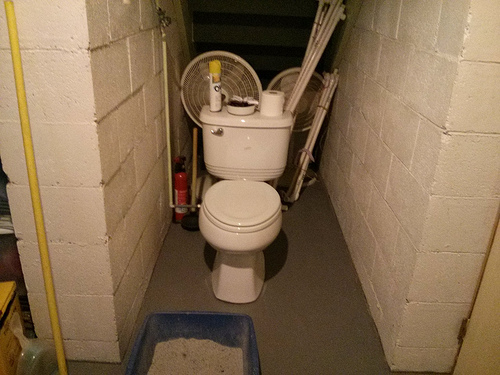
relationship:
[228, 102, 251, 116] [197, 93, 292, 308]
ashtray on top of toilet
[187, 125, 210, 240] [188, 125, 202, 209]
plunger has handle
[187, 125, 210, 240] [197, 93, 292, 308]
plunger by toilet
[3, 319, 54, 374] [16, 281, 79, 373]
dust pan in corner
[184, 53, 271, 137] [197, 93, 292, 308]
fan behind toilet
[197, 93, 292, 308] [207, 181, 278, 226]
toilet has lid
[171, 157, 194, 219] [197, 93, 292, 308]
fire extinguisher next to toilet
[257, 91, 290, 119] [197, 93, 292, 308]
toilet paper on top of toilet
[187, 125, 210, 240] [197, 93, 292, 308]
plunger behind toilet